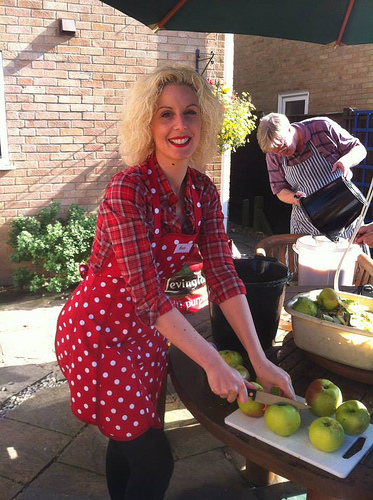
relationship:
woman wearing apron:
[56, 61, 296, 499] [55, 165, 202, 440]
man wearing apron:
[256, 112, 366, 235] [282, 139, 370, 234]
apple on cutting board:
[309, 416, 345, 453] [223, 393, 372, 479]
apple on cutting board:
[306, 377, 342, 417] [223, 393, 372, 479]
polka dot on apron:
[110, 358, 118, 367] [55, 165, 202, 440]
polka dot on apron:
[71, 336, 170, 439] [55, 165, 202, 440]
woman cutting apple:
[56, 61, 296, 499] [264, 403, 300, 436]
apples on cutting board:
[237, 378, 369, 451] [223, 393, 372, 479]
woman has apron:
[56, 61, 296, 499] [55, 165, 202, 440]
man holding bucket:
[256, 112, 366, 235] [299, 177, 367, 242]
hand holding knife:
[206, 363, 247, 403] [245, 387, 314, 411]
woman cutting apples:
[56, 61, 296, 499] [237, 378, 369, 451]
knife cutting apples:
[245, 387, 314, 411] [237, 378, 369, 451]